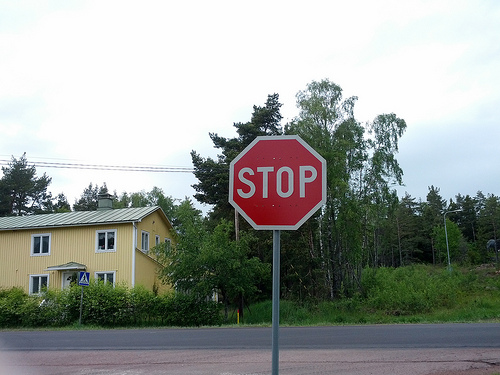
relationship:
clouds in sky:
[97, 45, 237, 132] [2, 1, 497, 208]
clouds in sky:
[97, 45, 392, 183] [388, 45, 494, 220]